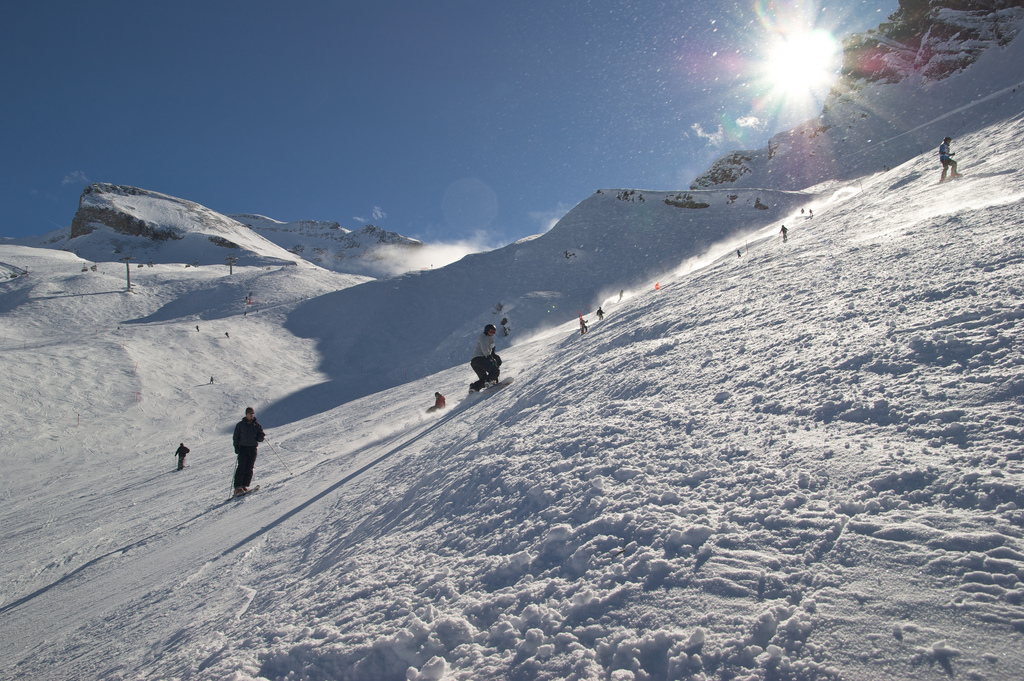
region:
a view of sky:
[258, 72, 437, 134]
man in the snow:
[446, 284, 522, 446]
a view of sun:
[694, 44, 897, 182]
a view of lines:
[151, 452, 396, 586]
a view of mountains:
[117, 151, 501, 427]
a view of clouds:
[398, 83, 554, 145]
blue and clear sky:
[260, 12, 517, 164]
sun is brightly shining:
[661, 3, 830, 108]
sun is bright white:
[710, 26, 844, 113]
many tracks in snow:
[444, 328, 836, 655]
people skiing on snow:
[96, 275, 596, 491]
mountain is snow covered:
[0, 155, 277, 345]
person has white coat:
[456, 307, 532, 371]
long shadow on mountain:
[260, 173, 666, 418]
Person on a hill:
[210, 387, 274, 509]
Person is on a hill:
[215, 389, 286, 510]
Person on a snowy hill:
[219, 394, 280, 509]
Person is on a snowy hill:
[225, 397, 284, 506]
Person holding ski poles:
[223, 431, 304, 498]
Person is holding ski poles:
[225, 434, 303, 492]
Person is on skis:
[213, 476, 268, 511]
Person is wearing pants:
[229, 433, 265, 501]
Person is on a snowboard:
[459, 364, 520, 406]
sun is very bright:
[686, 5, 868, 152]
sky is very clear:
[6, 2, 905, 247]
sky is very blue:
[3, 3, 908, 253]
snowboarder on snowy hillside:
[456, 317, 513, 393]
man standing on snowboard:
[221, 396, 276, 504]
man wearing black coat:
[229, 416, 269, 462]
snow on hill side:
[3, 53, 1022, 677]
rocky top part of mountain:
[831, 1, 1019, 118]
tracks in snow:
[228, 529, 274, 654]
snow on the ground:
[747, 553, 785, 588]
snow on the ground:
[917, 652, 941, 675]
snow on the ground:
[947, 383, 1018, 476]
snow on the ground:
[704, 567, 800, 669]